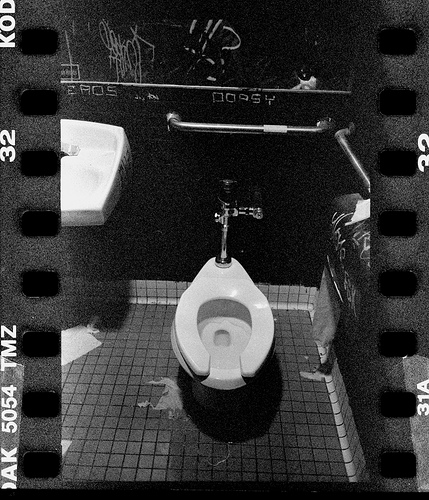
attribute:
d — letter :
[211, 91, 224, 104]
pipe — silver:
[215, 171, 261, 264]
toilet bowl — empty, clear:
[175, 295, 276, 369]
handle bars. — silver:
[161, 113, 335, 138]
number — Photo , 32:
[1, 128, 23, 168]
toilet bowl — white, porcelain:
[170, 255, 276, 406]